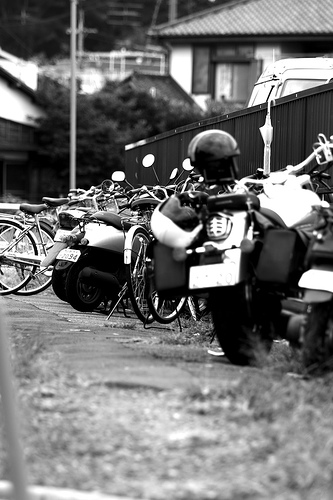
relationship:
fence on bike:
[122, 82, 333, 186] [187, 132, 330, 368]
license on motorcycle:
[55, 247, 81, 263] [59, 209, 152, 312]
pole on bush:
[70, 0, 78, 195] [95, 79, 215, 134]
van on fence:
[247, 54, 328, 108] [124, 78, 331, 195]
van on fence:
[247, 54, 333, 107] [122, 84, 331, 186]